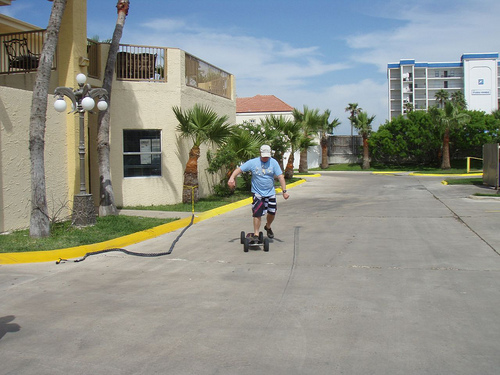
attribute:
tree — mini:
[171, 103, 235, 204]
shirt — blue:
[239, 158, 283, 199]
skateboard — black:
[239, 229, 269, 252]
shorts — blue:
[252, 192, 277, 217]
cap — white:
[260, 141, 271, 160]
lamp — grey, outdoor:
[55, 73, 112, 226]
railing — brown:
[1, 29, 231, 99]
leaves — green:
[173, 102, 234, 144]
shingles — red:
[234, 94, 296, 115]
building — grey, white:
[387, 52, 499, 123]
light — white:
[54, 99, 69, 113]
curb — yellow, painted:
[1, 181, 301, 266]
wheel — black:
[240, 229, 248, 244]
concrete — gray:
[0, 172, 500, 374]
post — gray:
[53, 86, 114, 225]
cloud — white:
[100, 15, 355, 94]